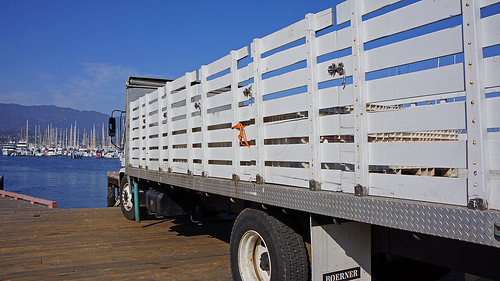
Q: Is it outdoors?
A: Yes, it is outdoors.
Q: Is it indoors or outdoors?
A: It is outdoors.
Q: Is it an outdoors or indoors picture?
A: It is outdoors.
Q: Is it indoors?
A: No, it is outdoors.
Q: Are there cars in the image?
A: No, there are no cars.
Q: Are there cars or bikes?
A: No, there are no cars or bikes.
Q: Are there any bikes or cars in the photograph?
A: No, there are no cars or bikes.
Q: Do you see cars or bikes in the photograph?
A: No, there are no cars or bikes.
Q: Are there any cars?
A: No, there are no cars.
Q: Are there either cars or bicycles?
A: No, there are no cars or bicycles.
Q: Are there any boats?
A: Yes, there is a boat.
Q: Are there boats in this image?
A: Yes, there is a boat.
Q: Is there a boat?
A: Yes, there is a boat.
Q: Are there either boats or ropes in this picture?
A: Yes, there is a boat.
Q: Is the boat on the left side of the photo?
A: Yes, the boat is on the left of the image.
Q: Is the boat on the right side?
A: No, the boat is on the left of the image.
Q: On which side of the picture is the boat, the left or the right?
A: The boat is on the left of the image.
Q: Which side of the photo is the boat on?
A: The boat is on the left of the image.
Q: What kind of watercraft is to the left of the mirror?
A: The watercraft is a boat.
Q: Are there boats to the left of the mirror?
A: Yes, there is a boat to the left of the mirror.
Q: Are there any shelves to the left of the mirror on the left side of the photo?
A: No, there is a boat to the left of the mirror.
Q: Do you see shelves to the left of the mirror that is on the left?
A: No, there is a boat to the left of the mirror.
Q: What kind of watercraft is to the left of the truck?
A: The watercraft is a boat.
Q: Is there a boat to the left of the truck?
A: Yes, there is a boat to the left of the truck.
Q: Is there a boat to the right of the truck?
A: No, the boat is to the left of the truck.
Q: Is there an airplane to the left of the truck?
A: No, there is a boat to the left of the truck.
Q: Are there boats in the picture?
A: Yes, there is a boat.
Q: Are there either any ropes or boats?
A: Yes, there is a boat.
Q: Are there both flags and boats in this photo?
A: No, there is a boat but no flags.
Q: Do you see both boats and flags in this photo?
A: No, there is a boat but no flags.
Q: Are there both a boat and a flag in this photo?
A: No, there is a boat but no flags.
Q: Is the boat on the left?
A: Yes, the boat is on the left of the image.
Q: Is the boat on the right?
A: No, the boat is on the left of the image.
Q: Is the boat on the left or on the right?
A: The boat is on the left of the image.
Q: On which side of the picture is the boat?
A: The boat is on the left of the image.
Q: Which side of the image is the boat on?
A: The boat is on the left of the image.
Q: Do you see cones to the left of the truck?
A: No, there is a boat to the left of the truck.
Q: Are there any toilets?
A: No, there are no toilets.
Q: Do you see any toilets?
A: No, there are no toilets.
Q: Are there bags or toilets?
A: No, there are no toilets or bags.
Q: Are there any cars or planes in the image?
A: No, there are no cars or planes.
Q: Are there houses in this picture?
A: No, there are no houses.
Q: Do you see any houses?
A: No, there are no houses.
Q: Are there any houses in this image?
A: No, there are no houses.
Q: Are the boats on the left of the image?
A: Yes, the boats are on the left of the image.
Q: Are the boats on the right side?
A: No, the boats are on the left of the image.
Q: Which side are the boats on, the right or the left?
A: The boats are on the left of the image.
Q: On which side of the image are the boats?
A: The boats are on the left of the image.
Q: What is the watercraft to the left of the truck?
A: The watercraft is boats.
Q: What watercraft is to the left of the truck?
A: The watercraft is boats.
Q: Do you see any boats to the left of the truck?
A: Yes, there are boats to the left of the truck.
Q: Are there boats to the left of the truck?
A: Yes, there are boats to the left of the truck.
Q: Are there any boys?
A: No, there are no boys.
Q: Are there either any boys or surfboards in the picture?
A: No, there are no boys or surfboards.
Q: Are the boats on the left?
A: Yes, the boats are on the left of the image.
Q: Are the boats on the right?
A: No, the boats are on the left of the image.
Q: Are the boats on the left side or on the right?
A: The boats are on the left of the image.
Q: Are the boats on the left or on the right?
A: The boats are on the left of the image.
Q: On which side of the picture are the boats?
A: The boats are on the left of the image.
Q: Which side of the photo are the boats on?
A: The boats are on the left of the image.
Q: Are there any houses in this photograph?
A: No, there are no houses.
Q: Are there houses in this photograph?
A: No, there are no houses.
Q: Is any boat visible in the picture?
A: Yes, there is a boat.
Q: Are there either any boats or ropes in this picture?
A: Yes, there is a boat.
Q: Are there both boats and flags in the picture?
A: No, there is a boat but no flags.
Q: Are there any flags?
A: No, there are no flags.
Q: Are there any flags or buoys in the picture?
A: No, there are no flags or buoys.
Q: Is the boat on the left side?
A: Yes, the boat is on the left of the image.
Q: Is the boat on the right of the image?
A: No, the boat is on the left of the image.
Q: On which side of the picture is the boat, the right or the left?
A: The boat is on the left of the image.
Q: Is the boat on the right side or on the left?
A: The boat is on the left of the image.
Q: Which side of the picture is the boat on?
A: The boat is on the left of the image.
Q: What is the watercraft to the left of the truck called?
A: The watercraft is a boat.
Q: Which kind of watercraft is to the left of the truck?
A: The watercraft is a boat.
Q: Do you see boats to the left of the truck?
A: Yes, there is a boat to the left of the truck.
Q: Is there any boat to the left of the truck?
A: Yes, there is a boat to the left of the truck.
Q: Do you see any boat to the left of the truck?
A: Yes, there is a boat to the left of the truck.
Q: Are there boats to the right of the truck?
A: No, the boat is to the left of the truck.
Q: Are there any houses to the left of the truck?
A: No, there is a boat to the left of the truck.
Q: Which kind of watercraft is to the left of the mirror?
A: The watercraft is a boat.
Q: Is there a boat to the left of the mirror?
A: Yes, there is a boat to the left of the mirror.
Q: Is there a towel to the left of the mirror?
A: No, there is a boat to the left of the mirror.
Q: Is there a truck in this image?
A: Yes, there is a truck.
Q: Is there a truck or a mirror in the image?
A: Yes, there is a truck.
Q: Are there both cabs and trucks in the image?
A: No, there is a truck but no taxis.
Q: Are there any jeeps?
A: No, there are no jeeps.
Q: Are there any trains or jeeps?
A: No, there are no jeeps or trains.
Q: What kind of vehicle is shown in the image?
A: The vehicle is a truck.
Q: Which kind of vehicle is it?
A: The vehicle is a truck.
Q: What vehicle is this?
A: This is a truck.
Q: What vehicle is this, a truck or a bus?
A: This is a truck.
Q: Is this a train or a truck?
A: This is a truck.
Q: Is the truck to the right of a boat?
A: Yes, the truck is to the right of a boat.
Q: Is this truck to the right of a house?
A: No, the truck is to the right of a boat.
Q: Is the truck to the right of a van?
A: No, the truck is to the right of a boat.